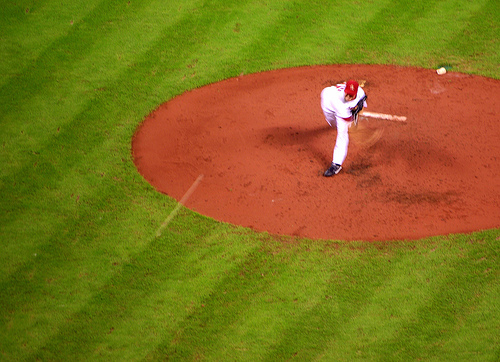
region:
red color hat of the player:
[343, 77, 358, 95]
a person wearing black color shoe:
[316, 158, 348, 178]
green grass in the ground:
[43, 38, 135, 285]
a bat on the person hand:
[353, 104, 411, 126]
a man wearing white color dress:
[313, 84, 358, 153]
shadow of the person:
[273, 112, 311, 155]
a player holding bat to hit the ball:
[321, 76, 378, 175]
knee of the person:
[335, 117, 348, 146]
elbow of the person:
[339, 111, 355, 123]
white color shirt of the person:
[323, 83, 373, 122]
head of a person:
[337, 56, 368, 110]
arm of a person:
[335, 82, 359, 119]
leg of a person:
[317, 118, 379, 165]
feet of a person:
[322, 162, 353, 174]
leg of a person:
[317, 102, 335, 129]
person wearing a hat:
[333, 72, 370, 100]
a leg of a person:
[326, 112, 372, 152]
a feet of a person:
[326, 158, 350, 173]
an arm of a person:
[337, 101, 374, 125]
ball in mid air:
[422, 46, 482, 84]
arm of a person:
[328, 95, 363, 136]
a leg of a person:
[320, 110, 388, 175]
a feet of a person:
[317, 155, 354, 177]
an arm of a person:
[340, 105, 353, 124]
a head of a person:
[336, 75, 376, 105]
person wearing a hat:
[288, 55, 423, 187]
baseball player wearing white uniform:
[317, 73, 367, 181]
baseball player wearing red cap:
[318, 78, 368, 181]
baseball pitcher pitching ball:
[320, 76, 366, 176]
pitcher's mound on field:
[123, 60, 499, 242]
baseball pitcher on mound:
[316, 75, 363, 175]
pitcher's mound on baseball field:
[130, 60, 496, 242]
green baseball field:
[5, 1, 497, 358]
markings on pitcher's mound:
[355, 103, 405, 119]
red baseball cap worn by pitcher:
[342, 76, 358, 97]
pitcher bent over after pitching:
[318, 77, 369, 177]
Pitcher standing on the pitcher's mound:
[127, 59, 498, 241]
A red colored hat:
[338, 76, 363, 100]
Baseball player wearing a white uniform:
[313, 73, 370, 179]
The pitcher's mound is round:
[129, 57, 498, 246]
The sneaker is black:
[318, 160, 347, 180]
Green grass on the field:
[1, 0, 498, 359]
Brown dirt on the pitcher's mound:
[129, 58, 498, 242]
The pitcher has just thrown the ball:
[310, 73, 371, 183]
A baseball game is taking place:
[2, 1, 497, 360]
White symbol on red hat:
[339, 76, 362, 100]